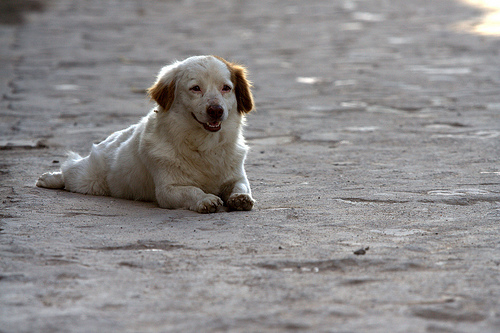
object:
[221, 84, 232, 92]
eye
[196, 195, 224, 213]
paw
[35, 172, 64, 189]
back paw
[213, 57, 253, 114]
ear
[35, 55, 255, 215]
dog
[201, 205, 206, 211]
claws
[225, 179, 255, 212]
legs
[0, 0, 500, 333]
photo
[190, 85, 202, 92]
eye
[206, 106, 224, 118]
nose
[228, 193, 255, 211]
paw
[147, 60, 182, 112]
ear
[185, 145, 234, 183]
chest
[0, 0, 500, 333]
dirt ground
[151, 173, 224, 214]
leg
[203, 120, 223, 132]
mouth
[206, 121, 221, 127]
teeth